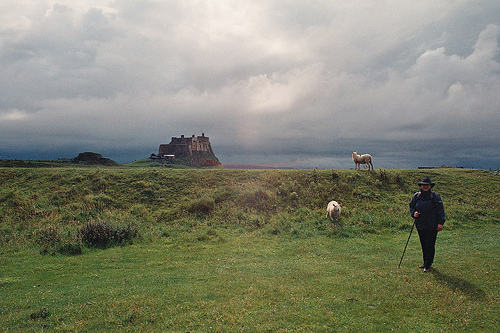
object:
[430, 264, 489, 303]
shadow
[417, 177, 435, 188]
hat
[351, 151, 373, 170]
lamb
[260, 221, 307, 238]
grass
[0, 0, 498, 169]
blue sky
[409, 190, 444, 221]
shirt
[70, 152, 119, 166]
hill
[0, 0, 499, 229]
background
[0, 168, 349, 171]
pathway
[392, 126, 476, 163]
waters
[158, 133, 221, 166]
castle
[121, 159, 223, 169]
hill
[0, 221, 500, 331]
field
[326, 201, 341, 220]
lamb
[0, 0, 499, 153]
cloud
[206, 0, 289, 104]
sun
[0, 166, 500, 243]
hill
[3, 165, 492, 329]
hillside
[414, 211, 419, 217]
hand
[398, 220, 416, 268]
cane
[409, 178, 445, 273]
man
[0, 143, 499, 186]
embankment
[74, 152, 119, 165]
another